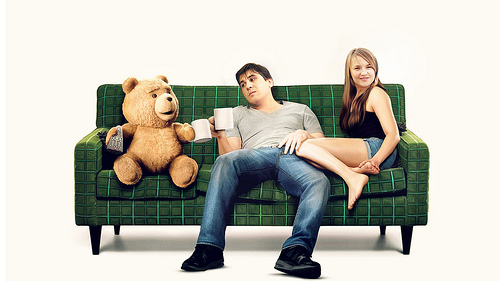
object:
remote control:
[105, 124, 126, 154]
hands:
[105, 126, 118, 145]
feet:
[343, 173, 370, 210]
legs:
[113, 224, 121, 235]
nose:
[245, 81, 254, 90]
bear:
[104, 74, 196, 188]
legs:
[178, 146, 277, 272]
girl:
[294, 47, 400, 211]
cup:
[213, 106, 236, 130]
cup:
[186, 118, 213, 143]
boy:
[179, 61, 332, 279]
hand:
[277, 128, 309, 155]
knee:
[293, 137, 326, 158]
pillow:
[194, 163, 294, 203]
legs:
[400, 224, 414, 256]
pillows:
[95, 163, 204, 202]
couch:
[71, 83, 431, 255]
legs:
[88, 224, 103, 255]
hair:
[234, 63, 273, 85]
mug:
[182, 119, 213, 144]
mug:
[213, 108, 236, 132]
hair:
[338, 48, 385, 134]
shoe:
[179, 244, 227, 273]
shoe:
[274, 246, 325, 279]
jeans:
[194, 144, 333, 257]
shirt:
[215, 100, 324, 149]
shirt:
[338, 90, 387, 139]